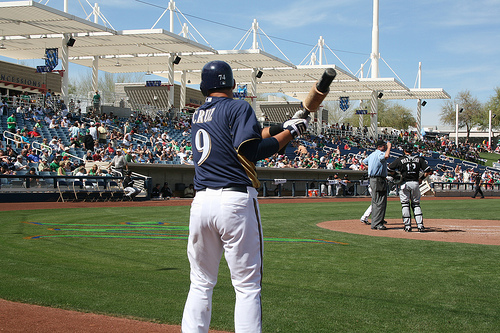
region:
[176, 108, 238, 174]
his shirt has a number 9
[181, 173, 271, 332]
the player is wearing white pants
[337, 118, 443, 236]
two men talking on the field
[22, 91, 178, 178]
people in their seats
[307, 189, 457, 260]
the men are standing in dirt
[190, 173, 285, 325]
the man's pants have a line down them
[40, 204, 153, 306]
this is a baseball field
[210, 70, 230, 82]
number seventy four helmet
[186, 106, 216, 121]
white lettering on shirt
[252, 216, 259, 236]
blue strip on pants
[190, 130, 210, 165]
number nine on shirt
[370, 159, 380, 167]
man wearing light blue shirt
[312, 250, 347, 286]
green grass in field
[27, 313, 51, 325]
brown dirt in field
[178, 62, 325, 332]
baseball player up to bat at a baseball game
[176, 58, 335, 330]
baseball player holding a bat up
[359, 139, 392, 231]
umpire for the baseball game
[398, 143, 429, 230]
catcher for the baseball game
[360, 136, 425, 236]
umpire talking to the catcher at a baseball game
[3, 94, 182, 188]
crowd in a stadium watching a baseball game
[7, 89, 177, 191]
people in a stadium watching a baseball game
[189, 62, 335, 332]
Hitter practicing hitting with a weight on his bat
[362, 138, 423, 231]
umpire talking to a cather in a baseball game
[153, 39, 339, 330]
a baseball player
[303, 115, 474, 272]
baseball players on the field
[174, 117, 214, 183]
the number 9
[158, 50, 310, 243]
a guy wearing a helmet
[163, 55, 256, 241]
a guy wearing a jersey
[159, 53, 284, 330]
a guy wearing white pants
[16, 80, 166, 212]
people watching a baseball game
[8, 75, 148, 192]
people sitting on bleachers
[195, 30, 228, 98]
batter has blue helmet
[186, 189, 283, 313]
batter has white pants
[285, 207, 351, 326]
green grass on field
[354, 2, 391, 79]
white pole behind field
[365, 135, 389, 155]
umpire has black mask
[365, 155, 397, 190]
umpire has blue shirt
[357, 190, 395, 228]
umpire has grey pants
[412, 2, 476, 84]
thin clouds in sky